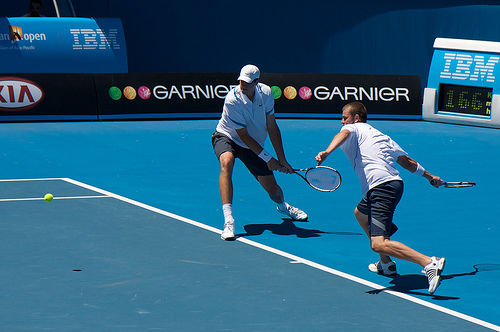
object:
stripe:
[371, 217, 386, 232]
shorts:
[356, 180, 404, 238]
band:
[413, 162, 426, 177]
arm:
[394, 142, 430, 178]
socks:
[222, 203, 234, 223]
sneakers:
[221, 224, 236, 240]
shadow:
[365, 263, 500, 301]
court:
[0, 119, 499, 329]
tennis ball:
[43, 193, 53, 203]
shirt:
[339, 122, 408, 198]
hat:
[237, 64, 261, 83]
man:
[210, 64, 308, 242]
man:
[314, 101, 443, 297]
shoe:
[421, 256, 446, 296]